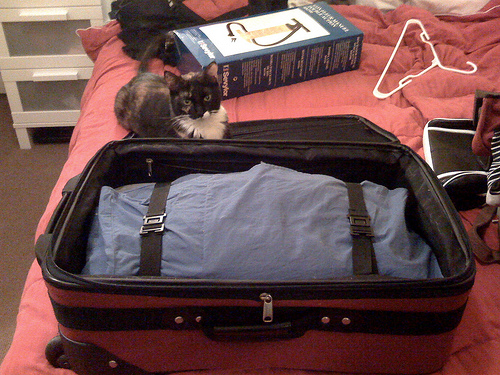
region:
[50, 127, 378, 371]
pink suitcase on bed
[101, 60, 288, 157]
black and white cat laying on suitcase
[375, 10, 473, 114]
white clothes hanger on pink blanket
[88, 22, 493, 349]
pink comforter on bed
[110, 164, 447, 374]
blue cloth in pink suitcase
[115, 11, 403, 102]
box with air pump on it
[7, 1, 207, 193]
white nightstand next to bed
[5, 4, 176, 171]
white night stand has two drawers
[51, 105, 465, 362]
blue cloth strapped down in pink suitcase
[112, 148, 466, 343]
pink suitcase has four metal buttons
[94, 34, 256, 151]
A BLACK AND WHITE CAT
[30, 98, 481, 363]
AN OPEN SUITCASE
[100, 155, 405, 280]
BLACK SUITCASE STRAPS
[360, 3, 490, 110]
A WHITE CLOTHES HANGER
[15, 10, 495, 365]
A PEACH BEDSPREAD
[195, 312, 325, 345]
A SUITCASE HANDLE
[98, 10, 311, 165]
CAT SITTING ON A SUITCASE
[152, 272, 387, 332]
A SUITCASE ZIPPER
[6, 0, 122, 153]
A WHITE NIGHT STAND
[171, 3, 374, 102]
A BOX ON THE BED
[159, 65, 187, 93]
the ear of a cat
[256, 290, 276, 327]
a silver metal zipper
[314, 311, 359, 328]
two bolts in the suitcase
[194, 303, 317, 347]
a black handle on the suitcase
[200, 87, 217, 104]
the eye of a cat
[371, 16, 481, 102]
a white coat hanger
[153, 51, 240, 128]
the head of a cat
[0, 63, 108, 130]
a white drawer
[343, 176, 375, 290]
a black strap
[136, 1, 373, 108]
a blue box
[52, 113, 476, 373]
a suitcase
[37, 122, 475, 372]
a piece of luggage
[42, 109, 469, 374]
the suitcase is red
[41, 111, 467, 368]
the suitcase is open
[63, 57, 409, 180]
a cat sits on the open suitcase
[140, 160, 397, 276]
straps hold an item in the suitcase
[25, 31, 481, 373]
the suitcase is on a bed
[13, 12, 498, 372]
a red blanket covers the bed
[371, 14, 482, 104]
a white coat hanger is on the bed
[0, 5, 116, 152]
a white table with drawers is next to the bed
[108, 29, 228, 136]
a pussy cat is laying on the luggage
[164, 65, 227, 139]
the cat has a white chest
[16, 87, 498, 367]
the luggage is open on a bed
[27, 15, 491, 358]
the coverlet on the bed is dusty pink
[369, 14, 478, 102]
a white hanger is on the bed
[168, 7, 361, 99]
a box is on the bed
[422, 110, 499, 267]
a black and white purse is on the bed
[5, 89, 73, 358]
the floor is carpeted in beige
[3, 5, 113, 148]
a white bedside table is in the room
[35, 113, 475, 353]
the pink suitcase is unzipped